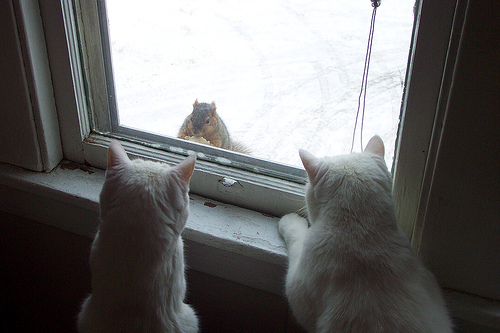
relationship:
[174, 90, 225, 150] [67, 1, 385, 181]
rodent looking into window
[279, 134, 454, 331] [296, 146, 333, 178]
cat has ear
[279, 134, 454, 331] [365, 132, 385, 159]
cat has ear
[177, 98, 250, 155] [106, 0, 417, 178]
rodent outside of window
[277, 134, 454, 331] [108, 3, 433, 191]
cat looking outside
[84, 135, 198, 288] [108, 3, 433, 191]
cats looking outside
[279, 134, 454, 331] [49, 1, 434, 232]
cat with paw on window